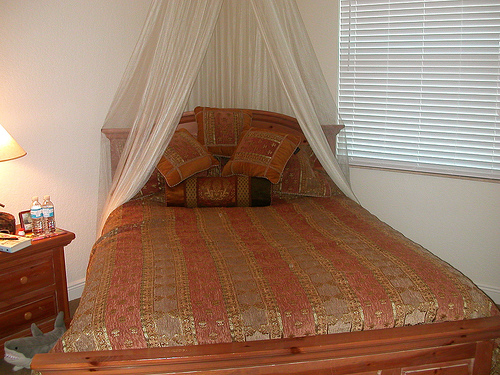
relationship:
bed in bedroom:
[31, 101, 500, 374] [3, 4, 497, 373]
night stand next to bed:
[0, 227, 77, 356] [31, 101, 500, 374]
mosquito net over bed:
[93, 0, 361, 239] [31, 101, 500, 374]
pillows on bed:
[111, 106, 345, 207] [31, 101, 500, 374]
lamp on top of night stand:
[2, 130, 28, 233] [0, 227, 77, 356]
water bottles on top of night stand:
[31, 194, 59, 238] [0, 227, 77, 356]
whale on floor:
[4, 310, 67, 371] [1, 297, 87, 374]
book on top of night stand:
[0, 232, 33, 254] [0, 227, 77, 356]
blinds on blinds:
[336, 0, 500, 183] [336, 0, 499, 184]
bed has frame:
[31, 101, 500, 374] [102, 117, 345, 195]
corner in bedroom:
[56, 1, 402, 311] [3, 4, 497, 373]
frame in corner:
[102, 117, 345, 195] [56, 1, 402, 311]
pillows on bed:
[156, 106, 303, 187] [31, 101, 500, 374]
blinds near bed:
[336, 0, 500, 183] [31, 101, 500, 374]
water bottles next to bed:
[31, 194, 59, 238] [31, 101, 500, 374]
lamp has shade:
[2, 130, 28, 233] [1, 126, 26, 163]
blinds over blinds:
[336, 0, 500, 183] [336, 0, 499, 184]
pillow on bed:
[163, 175, 272, 206] [31, 101, 500, 374]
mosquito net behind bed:
[93, 0, 361, 239] [31, 101, 500, 374]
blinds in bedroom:
[336, 0, 500, 183] [3, 4, 497, 373]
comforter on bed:
[48, 191, 500, 353] [31, 101, 500, 374]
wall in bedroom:
[4, 3, 497, 304] [3, 4, 497, 373]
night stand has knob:
[0, 227, 77, 356] [18, 274, 29, 287]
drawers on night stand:
[0, 251, 60, 346] [0, 227, 77, 356]